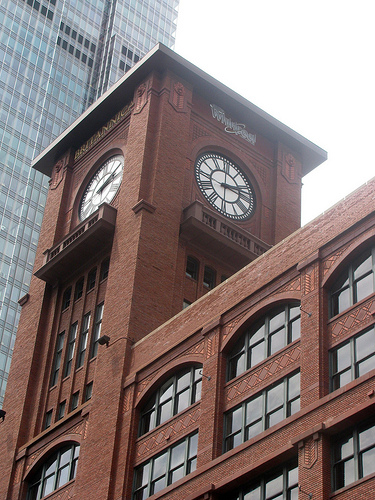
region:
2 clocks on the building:
[71, 136, 262, 234]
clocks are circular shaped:
[75, 151, 260, 223]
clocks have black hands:
[71, 149, 261, 233]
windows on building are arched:
[12, 238, 373, 495]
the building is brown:
[6, 43, 370, 498]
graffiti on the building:
[204, 96, 266, 148]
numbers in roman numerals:
[192, 148, 256, 222]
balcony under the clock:
[183, 195, 270, 259]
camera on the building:
[90, 325, 131, 351]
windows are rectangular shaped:
[35, 255, 229, 417]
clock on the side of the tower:
[192, 146, 264, 225]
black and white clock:
[69, 146, 135, 225]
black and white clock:
[195, 143, 268, 229]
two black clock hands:
[93, 159, 124, 198]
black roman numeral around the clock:
[193, 143, 259, 226]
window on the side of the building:
[124, 430, 203, 498]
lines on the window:
[216, 368, 303, 452]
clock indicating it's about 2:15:
[193, 149, 263, 225]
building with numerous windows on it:
[1, 0, 177, 411]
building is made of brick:
[1, 41, 374, 497]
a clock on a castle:
[201, 151, 256, 218]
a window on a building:
[219, 313, 309, 367]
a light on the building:
[97, 334, 110, 348]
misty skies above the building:
[204, 0, 350, 99]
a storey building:
[2, 2, 93, 113]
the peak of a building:
[147, 36, 168, 64]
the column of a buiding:
[301, 263, 322, 417]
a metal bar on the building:
[298, 303, 311, 316]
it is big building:
[11, 22, 374, 497]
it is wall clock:
[191, 144, 261, 228]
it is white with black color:
[195, 148, 258, 228]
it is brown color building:
[131, 100, 165, 321]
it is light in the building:
[93, 327, 111, 357]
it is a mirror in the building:
[234, 407, 285, 420]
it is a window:
[215, 299, 303, 383]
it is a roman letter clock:
[190, 148, 263, 224]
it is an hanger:
[294, 301, 313, 322]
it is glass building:
[0, 4, 158, 122]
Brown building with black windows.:
[243, 351, 291, 489]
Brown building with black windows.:
[308, 270, 350, 320]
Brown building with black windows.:
[309, 329, 342, 390]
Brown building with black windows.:
[47, 339, 117, 395]